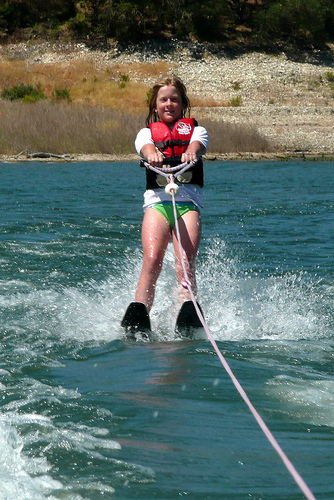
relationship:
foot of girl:
[123, 298, 159, 339] [123, 76, 209, 334]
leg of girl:
[173, 206, 219, 326] [133, 75, 209, 317]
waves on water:
[61, 348, 311, 372] [0, 158, 334, 497]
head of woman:
[151, 76, 185, 124] [134, 75, 207, 313]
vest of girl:
[143, 115, 204, 188] [133, 75, 209, 317]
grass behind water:
[0, 51, 302, 153] [0, 158, 334, 497]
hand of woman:
[180, 148, 200, 164] [123, 77, 210, 334]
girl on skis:
[133, 75, 209, 317] [121, 302, 151, 330]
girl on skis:
[133, 75, 209, 317] [178, 297, 204, 328]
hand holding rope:
[146, 151, 163, 166] [162, 196, 245, 358]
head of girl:
[145, 76, 191, 124] [133, 75, 209, 317]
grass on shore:
[1, 57, 269, 155] [2, 147, 329, 164]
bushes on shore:
[18, 70, 69, 114] [4, 149, 332, 162]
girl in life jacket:
[94, 74, 220, 323] [144, 118, 204, 193]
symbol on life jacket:
[174, 118, 195, 136] [149, 120, 200, 187]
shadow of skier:
[102, 337, 204, 488] [125, 72, 213, 321]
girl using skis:
[133, 75, 209, 317] [118, 301, 152, 333]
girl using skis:
[133, 75, 209, 317] [173, 298, 203, 337]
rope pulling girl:
[167, 173, 316, 499] [133, 75, 209, 317]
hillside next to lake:
[103, 50, 319, 91] [116, 91, 324, 463]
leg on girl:
[169, 201, 201, 308] [133, 75, 209, 317]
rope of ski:
[136, 154, 316, 498] [118, 300, 154, 334]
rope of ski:
[136, 154, 316, 498] [171, 302, 208, 340]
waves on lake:
[30, 286, 112, 339] [0, 154, 333, 499]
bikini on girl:
[156, 201, 197, 224] [133, 75, 209, 317]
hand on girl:
[146, 152, 164, 165] [132, 78, 198, 319]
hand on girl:
[182, 131, 208, 165] [123, 76, 209, 334]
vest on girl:
[144, 117, 204, 192] [127, 69, 214, 335]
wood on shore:
[18, 147, 79, 158] [1, 153, 333, 162]